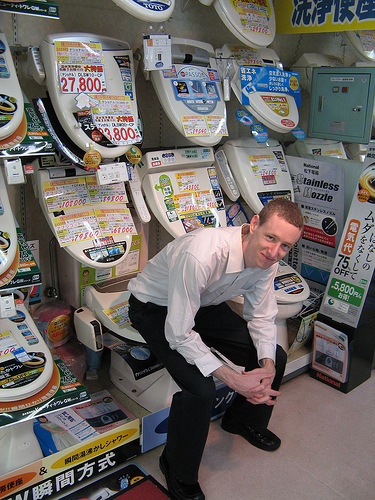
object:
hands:
[241, 367, 282, 405]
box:
[0, 388, 140, 499]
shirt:
[127, 223, 279, 378]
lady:
[38, 415, 80, 450]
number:
[61, 77, 101, 93]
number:
[337, 253, 350, 268]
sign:
[274, 0, 375, 35]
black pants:
[127, 293, 288, 500]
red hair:
[258, 197, 303, 229]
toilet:
[0, 32, 25, 143]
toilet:
[27, 32, 138, 160]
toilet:
[139, 33, 227, 147]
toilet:
[215, 42, 299, 134]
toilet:
[30, 155, 132, 269]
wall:
[0, 0, 375, 316]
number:
[79, 77, 86, 91]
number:
[87, 77, 94, 91]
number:
[94, 77, 101, 91]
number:
[61, 77, 68, 92]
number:
[68, 77, 75, 91]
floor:
[260, 451, 374, 500]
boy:
[126, 198, 304, 500]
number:
[98, 127, 136, 140]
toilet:
[74, 271, 182, 381]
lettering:
[291, 0, 375, 26]